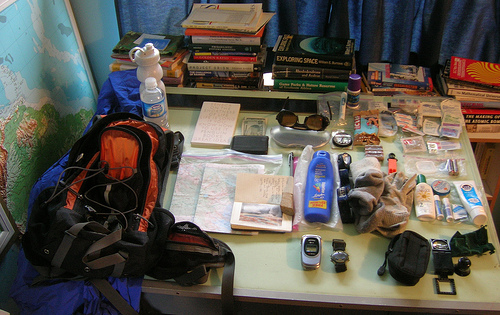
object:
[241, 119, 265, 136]
cash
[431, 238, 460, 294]
compass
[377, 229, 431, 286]
camera case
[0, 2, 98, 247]
wall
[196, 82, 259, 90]
books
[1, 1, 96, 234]
map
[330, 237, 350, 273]
watch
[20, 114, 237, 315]
backpack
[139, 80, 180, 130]
water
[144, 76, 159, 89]
cap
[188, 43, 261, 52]
books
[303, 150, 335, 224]
bottle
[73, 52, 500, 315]
desk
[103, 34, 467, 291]
clutter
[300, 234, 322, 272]
cell phone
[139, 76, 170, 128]
bottle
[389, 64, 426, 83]
map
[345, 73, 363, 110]
bottle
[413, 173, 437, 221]
bottle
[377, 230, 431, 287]
bag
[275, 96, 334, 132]
sunglasses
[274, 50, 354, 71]
book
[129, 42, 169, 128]
bottle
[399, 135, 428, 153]
medicines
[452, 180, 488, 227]
supply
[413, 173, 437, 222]
supply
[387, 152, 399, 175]
supply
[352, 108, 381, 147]
supply